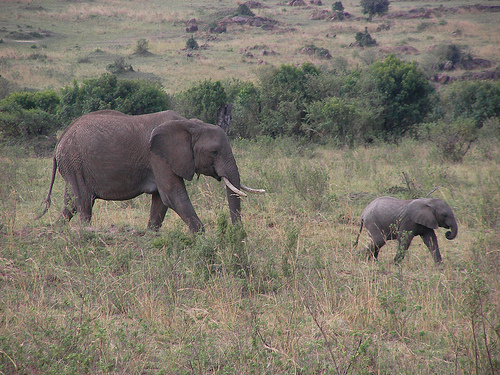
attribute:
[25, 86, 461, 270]
animals — walking, elephants, wild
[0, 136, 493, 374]
field — grassy, gray, brown, green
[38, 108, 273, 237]
elephant — large, gray, hairy, adult, walking, mother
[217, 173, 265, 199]
tusks — long, white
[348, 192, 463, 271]
elephant — baby, small, gray, tiny, walking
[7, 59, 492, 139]
trees — green, row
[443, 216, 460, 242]
trunk — gray, tiny, curled, small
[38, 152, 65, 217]
tail — thin, long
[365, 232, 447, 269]
legs — little, gray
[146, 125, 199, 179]
ear — gray, floppy, big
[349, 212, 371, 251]
tail — thin, little